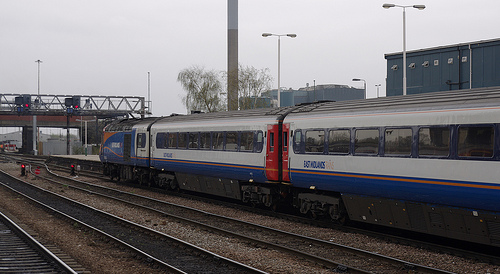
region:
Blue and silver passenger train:
[97, 85, 499, 251]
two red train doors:
[265, 122, 290, 182]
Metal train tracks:
[1, 150, 499, 271]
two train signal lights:
[15, 93, 32, 111]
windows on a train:
[136, 122, 498, 162]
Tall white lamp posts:
[261, 30, 298, 105]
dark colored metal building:
[383, 36, 498, 94]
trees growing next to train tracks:
[176, 65, 273, 110]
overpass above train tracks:
[1, 93, 152, 155]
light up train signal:
[18, 162, 26, 177]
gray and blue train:
[100, 103, 494, 230]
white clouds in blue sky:
[124, 21, 176, 59]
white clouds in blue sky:
[60, 26, 141, 61]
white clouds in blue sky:
[324, 22, 368, 53]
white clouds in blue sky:
[150, 35, 202, 59]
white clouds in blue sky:
[100, 23, 151, 58]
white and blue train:
[91, 109, 492, 211]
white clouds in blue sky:
[22, 32, 69, 70]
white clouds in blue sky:
[60, 35, 95, 56]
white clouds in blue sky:
[81, 45, 119, 90]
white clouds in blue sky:
[262, 16, 289, 43]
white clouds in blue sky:
[117, 39, 149, 61]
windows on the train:
[154, 127, 265, 153]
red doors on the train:
[263, 123, 294, 180]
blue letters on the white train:
[299, 157, 326, 169]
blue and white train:
[98, 82, 498, 254]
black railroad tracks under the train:
[0, 147, 495, 272]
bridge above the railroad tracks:
[1, 91, 151, 128]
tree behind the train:
[173, 62, 274, 114]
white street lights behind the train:
[261, 30, 299, 105]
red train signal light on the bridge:
[20, 92, 33, 112]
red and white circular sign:
[31, 165, 44, 177]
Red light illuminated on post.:
[66, 159, 81, 172]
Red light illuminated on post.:
[15, 157, 37, 181]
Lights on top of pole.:
[258, 22, 318, 47]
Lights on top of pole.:
[379, 3, 441, 30]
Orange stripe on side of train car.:
[349, 166, 441, 193]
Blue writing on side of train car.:
[294, 154, 334, 168]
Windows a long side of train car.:
[318, 130, 430, 157]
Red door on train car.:
[265, 120, 315, 180]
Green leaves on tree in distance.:
[183, 72, 243, 111]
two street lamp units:
[260, 0, 433, 110]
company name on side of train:
[299, 157, 337, 172]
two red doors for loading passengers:
[265, 122, 292, 184]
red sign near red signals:
[33, 168, 40, 176]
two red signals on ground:
[18, 162, 75, 172]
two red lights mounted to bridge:
[23, 100, 80, 111]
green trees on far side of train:
[175, 59, 276, 117]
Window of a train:
[456, 125, 492, 158]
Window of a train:
[418, 125, 449, 155]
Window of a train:
[383, 125, 410, 155]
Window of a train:
[355, 127, 377, 154]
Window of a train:
[328, 128, 347, 154]